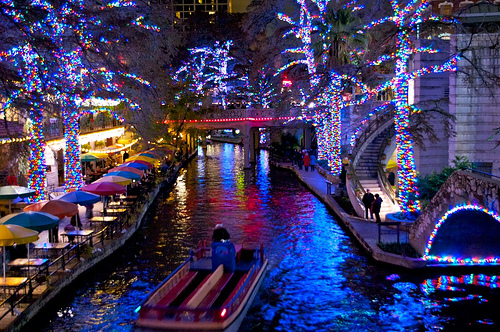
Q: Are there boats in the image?
A: Yes, there is a boat.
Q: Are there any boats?
A: Yes, there is a boat.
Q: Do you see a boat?
A: Yes, there is a boat.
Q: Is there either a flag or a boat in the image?
A: Yes, there is a boat.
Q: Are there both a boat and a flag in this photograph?
A: No, there is a boat but no flags.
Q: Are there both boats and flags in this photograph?
A: No, there is a boat but no flags.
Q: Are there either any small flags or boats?
A: Yes, there is a small boat.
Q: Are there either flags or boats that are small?
A: Yes, the boat is small.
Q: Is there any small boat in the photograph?
A: Yes, there is a small boat.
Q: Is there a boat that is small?
A: Yes, there is a boat that is small.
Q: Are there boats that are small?
A: Yes, there is a boat that is small.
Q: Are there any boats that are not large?
A: Yes, there is a small boat.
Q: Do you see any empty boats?
A: Yes, there is an empty boat.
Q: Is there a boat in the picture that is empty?
A: Yes, there is a boat that is empty.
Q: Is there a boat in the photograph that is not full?
A: Yes, there is a empty boat.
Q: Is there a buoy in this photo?
A: No, there are no buoys.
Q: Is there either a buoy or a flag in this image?
A: No, there are no buoys or flags.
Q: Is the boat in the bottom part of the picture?
A: Yes, the boat is in the bottom of the image.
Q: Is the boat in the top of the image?
A: No, the boat is in the bottom of the image.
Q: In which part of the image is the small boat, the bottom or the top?
A: The boat is in the bottom of the image.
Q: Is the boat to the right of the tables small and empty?
A: Yes, the boat is small and empty.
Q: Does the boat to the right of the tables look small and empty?
A: Yes, the boat is small and empty.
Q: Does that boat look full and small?
A: No, the boat is small but empty.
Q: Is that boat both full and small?
A: No, the boat is small but empty.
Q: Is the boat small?
A: Yes, the boat is small.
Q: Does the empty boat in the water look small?
A: Yes, the boat is small.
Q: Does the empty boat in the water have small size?
A: Yes, the boat is small.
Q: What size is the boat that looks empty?
A: The boat is small.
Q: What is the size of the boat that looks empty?
A: The boat is small.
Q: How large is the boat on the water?
A: The boat is small.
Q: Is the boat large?
A: No, the boat is small.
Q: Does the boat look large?
A: No, the boat is small.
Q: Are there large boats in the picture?
A: No, there is a boat but it is small.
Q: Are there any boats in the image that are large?
A: No, there is a boat but it is small.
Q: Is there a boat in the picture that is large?
A: No, there is a boat but it is small.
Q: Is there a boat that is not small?
A: No, there is a boat but it is small.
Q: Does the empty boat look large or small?
A: The boat is small.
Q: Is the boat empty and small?
A: Yes, the boat is empty and small.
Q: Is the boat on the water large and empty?
A: No, the boat is empty but small.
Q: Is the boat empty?
A: Yes, the boat is empty.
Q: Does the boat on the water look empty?
A: Yes, the boat is empty.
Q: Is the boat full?
A: No, the boat is empty.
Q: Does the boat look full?
A: No, the boat is empty.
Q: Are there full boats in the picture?
A: No, there is a boat but it is empty.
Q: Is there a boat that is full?
A: No, there is a boat but it is empty.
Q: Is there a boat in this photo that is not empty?
A: No, there is a boat but it is empty.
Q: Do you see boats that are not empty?
A: No, there is a boat but it is empty.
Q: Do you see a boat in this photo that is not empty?
A: No, there is a boat but it is empty.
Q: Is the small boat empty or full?
A: The boat is empty.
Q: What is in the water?
A: The boat is in the water.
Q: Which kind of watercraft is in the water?
A: The watercraft is a boat.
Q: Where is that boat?
A: The boat is in the water.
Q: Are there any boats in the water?
A: Yes, there is a boat in the water.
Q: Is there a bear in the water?
A: No, there is a boat in the water.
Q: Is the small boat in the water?
A: Yes, the boat is in the water.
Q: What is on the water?
A: The boat is on the water.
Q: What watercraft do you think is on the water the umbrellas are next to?
A: The watercraft is a boat.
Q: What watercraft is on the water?
A: The watercraft is a boat.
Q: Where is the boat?
A: The boat is on the water.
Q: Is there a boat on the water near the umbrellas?
A: Yes, there is a boat on the water.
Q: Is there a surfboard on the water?
A: No, there is a boat on the water.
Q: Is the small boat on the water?
A: Yes, the boat is on the water.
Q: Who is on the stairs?
A: The people are on the stairs.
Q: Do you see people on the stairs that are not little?
A: Yes, there are people on the stairs.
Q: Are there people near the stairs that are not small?
A: Yes, there are people near the stairs.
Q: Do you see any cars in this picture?
A: No, there are no cars.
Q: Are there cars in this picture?
A: No, there are no cars.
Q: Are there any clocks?
A: No, there are no clocks.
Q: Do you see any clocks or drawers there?
A: No, there are no clocks or drawers.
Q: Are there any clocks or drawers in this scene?
A: No, there are no clocks or drawers.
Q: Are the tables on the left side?
A: Yes, the tables are on the left of the image.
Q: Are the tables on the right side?
A: No, the tables are on the left of the image.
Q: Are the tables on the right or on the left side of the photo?
A: The tables are on the left of the image.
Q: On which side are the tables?
A: The tables are on the left of the image.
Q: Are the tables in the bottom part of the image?
A: Yes, the tables are in the bottom of the image.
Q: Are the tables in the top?
A: No, the tables are in the bottom of the image.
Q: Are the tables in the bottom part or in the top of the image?
A: The tables are in the bottom of the image.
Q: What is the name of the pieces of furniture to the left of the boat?
A: The pieces of furniture are tables.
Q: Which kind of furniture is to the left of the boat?
A: The pieces of furniture are tables.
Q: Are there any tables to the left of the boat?
A: Yes, there are tables to the left of the boat.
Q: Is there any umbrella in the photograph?
A: Yes, there are umbrellas.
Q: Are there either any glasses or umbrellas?
A: Yes, there are umbrellas.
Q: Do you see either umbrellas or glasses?
A: Yes, there are umbrellas.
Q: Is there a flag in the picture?
A: No, there are no flags.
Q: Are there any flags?
A: No, there are no flags.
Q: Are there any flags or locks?
A: No, there are no flags or locks.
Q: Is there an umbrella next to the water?
A: Yes, there are umbrellas next to the water.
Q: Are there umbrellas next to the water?
A: Yes, there are umbrellas next to the water.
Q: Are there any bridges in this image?
A: Yes, there is a bridge.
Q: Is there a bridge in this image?
A: Yes, there is a bridge.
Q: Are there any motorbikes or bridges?
A: Yes, there is a bridge.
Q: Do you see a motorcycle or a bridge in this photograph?
A: Yes, there is a bridge.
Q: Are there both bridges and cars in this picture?
A: No, there is a bridge but no cars.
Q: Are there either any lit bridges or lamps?
A: Yes, there is a lit bridge.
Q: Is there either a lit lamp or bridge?
A: Yes, there is a lit bridge.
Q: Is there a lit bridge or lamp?
A: Yes, there is a lit bridge.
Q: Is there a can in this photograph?
A: No, there are no cans.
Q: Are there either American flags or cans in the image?
A: No, there are no cans or American flags.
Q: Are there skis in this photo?
A: No, there are no skis.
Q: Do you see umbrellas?
A: Yes, there is an umbrella.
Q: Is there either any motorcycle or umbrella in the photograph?
A: Yes, there is an umbrella.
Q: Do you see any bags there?
A: No, there are no bags.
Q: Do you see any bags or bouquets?
A: No, there are no bags or bouquets.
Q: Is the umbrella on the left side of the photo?
A: Yes, the umbrella is on the left of the image.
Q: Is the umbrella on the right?
A: No, the umbrella is on the left of the image.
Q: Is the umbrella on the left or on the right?
A: The umbrella is on the left of the image.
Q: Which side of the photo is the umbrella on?
A: The umbrella is on the left of the image.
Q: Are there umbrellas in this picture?
A: Yes, there is an umbrella.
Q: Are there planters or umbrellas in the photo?
A: Yes, there is an umbrella.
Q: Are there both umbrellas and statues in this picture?
A: No, there is an umbrella but no statues.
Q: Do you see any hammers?
A: No, there are no hammers.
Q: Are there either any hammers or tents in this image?
A: No, there are no hammers or tents.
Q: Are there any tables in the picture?
A: Yes, there is a table.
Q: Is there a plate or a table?
A: Yes, there is a table.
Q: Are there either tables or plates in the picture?
A: Yes, there is a table.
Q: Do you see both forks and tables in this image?
A: No, there is a table but no forks.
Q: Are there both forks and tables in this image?
A: No, there is a table but no forks.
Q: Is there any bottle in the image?
A: No, there are no bottles.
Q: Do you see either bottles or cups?
A: No, there are no bottles or cups.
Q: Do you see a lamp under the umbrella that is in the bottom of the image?
A: No, there is a table under the umbrella.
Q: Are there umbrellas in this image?
A: Yes, there is an umbrella.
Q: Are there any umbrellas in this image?
A: Yes, there is an umbrella.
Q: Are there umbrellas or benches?
A: Yes, there is an umbrella.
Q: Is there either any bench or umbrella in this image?
A: Yes, there is an umbrella.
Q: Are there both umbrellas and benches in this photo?
A: No, there is an umbrella but no benches.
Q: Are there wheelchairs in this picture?
A: No, there are no wheelchairs.